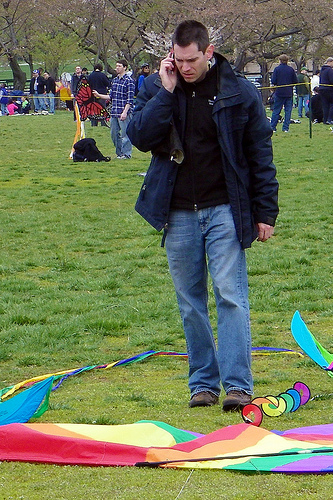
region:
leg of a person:
[161, 265, 207, 392]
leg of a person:
[204, 246, 267, 356]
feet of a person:
[184, 376, 225, 406]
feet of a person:
[222, 386, 257, 413]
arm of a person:
[133, 54, 187, 134]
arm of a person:
[226, 111, 314, 208]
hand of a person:
[152, 52, 190, 93]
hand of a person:
[242, 215, 291, 248]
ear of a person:
[197, 36, 226, 68]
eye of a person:
[169, 50, 196, 67]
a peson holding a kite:
[54, 49, 131, 115]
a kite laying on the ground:
[5, 351, 192, 481]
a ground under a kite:
[48, 355, 133, 474]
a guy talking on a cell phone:
[155, 36, 203, 95]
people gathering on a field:
[22, 59, 132, 104]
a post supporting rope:
[301, 76, 318, 140]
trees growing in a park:
[215, 2, 298, 58]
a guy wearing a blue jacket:
[209, 82, 295, 241]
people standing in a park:
[265, 56, 330, 127]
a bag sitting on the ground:
[59, 126, 120, 184]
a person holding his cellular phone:
[151, 37, 214, 82]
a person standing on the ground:
[114, 357, 255, 423]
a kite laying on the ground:
[18, 366, 89, 499]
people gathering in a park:
[23, 63, 132, 114]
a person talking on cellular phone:
[150, 28, 215, 96]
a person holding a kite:
[63, 65, 124, 109]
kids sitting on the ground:
[6, 94, 37, 125]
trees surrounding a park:
[8, 3, 280, 20]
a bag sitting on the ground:
[45, 138, 113, 174]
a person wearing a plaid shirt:
[110, 75, 141, 111]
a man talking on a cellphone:
[125, 19, 289, 156]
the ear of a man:
[204, 40, 216, 62]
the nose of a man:
[180, 60, 192, 72]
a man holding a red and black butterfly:
[69, 53, 137, 153]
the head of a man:
[111, 55, 130, 76]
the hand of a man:
[253, 215, 277, 247]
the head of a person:
[276, 51, 291, 68]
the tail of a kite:
[240, 377, 330, 429]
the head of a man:
[73, 63, 83, 74]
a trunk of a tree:
[8, 52, 25, 91]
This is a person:
[136, 16, 282, 420]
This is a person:
[98, 52, 138, 173]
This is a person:
[67, 72, 106, 128]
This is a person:
[38, 64, 59, 131]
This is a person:
[23, 64, 45, 115]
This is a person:
[261, 42, 301, 139]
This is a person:
[308, 45, 330, 149]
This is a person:
[58, 57, 87, 116]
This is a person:
[132, 50, 166, 112]